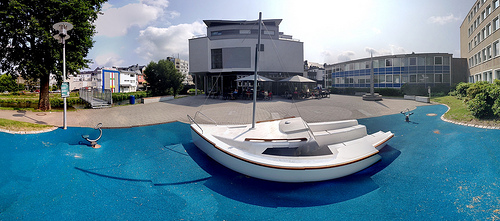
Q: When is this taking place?
A: Daytime.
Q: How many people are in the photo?
A: None.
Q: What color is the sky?
A: Blue and white.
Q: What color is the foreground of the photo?
A: Blue.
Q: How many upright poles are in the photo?
A: Two.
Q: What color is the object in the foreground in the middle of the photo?
A: White.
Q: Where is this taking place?
A: At a boat mooring.